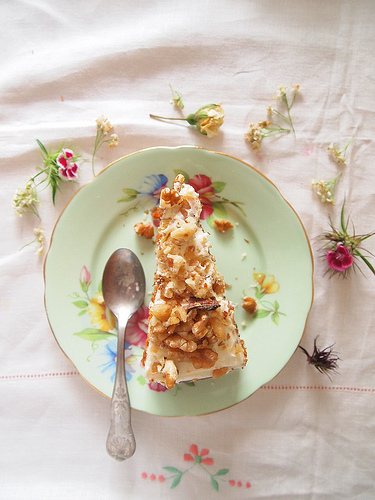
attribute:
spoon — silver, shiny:
[100, 250, 148, 459]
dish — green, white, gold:
[58, 136, 320, 416]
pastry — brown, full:
[155, 184, 241, 386]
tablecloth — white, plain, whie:
[4, 11, 341, 125]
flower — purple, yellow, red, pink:
[321, 214, 374, 259]